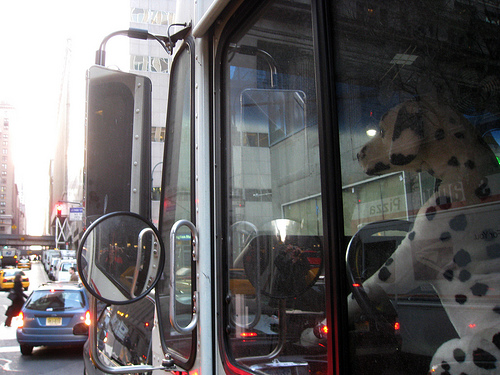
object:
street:
[0, 246, 87, 372]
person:
[5, 270, 30, 327]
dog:
[300, 100, 499, 374]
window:
[328, 1, 499, 374]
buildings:
[1, 0, 176, 265]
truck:
[54, 256, 85, 285]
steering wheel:
[339, 218, 435, 340]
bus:
[74, 1, 497, 373]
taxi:
[1, 266, 29, 291]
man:
[67, 266, 87, 285]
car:
[13, 283, 96, 355]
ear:
[390, 103, 428, 166]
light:
[10, 312, 36, 329]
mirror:
[75, 211, 166, 306]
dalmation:
[344, 109, 496, 334]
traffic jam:
[0, 244, 92, 359]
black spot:
[453, 250, 474, 268]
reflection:
[242, 218, 325, 302]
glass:
[213, 3, 329, 365]